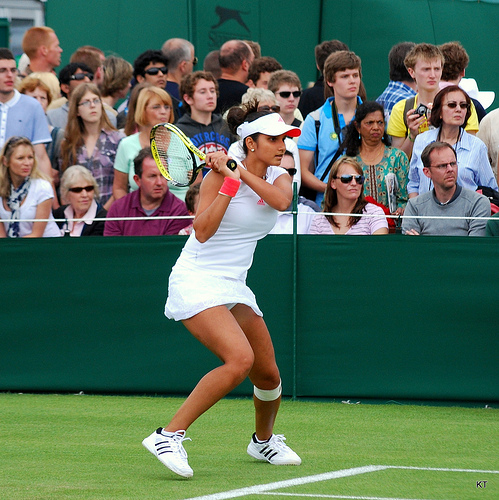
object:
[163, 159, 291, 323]
dress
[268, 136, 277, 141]
eye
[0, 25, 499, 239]
people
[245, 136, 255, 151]
ear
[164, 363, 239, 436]
shins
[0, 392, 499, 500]
tennis court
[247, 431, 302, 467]
tennis shoes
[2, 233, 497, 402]
bleachers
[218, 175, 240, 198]
wristband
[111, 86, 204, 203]
blonde woman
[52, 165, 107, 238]
woman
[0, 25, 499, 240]
spectator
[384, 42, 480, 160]
man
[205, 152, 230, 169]
hand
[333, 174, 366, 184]
sunglasses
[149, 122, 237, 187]
racket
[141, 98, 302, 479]
female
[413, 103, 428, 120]
camera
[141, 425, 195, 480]
pins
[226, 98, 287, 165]
head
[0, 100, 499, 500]
match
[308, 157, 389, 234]
woman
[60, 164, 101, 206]
hair